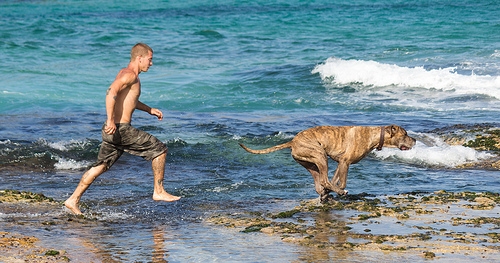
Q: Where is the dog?
A: To the right of the man.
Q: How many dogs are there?
A: One.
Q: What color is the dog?
A: Brown.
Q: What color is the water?
A: Blue and white.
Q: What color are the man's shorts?
A: Gray.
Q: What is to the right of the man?
A: The dog.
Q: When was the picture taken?
A: Daytime.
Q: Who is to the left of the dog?
A: The man.